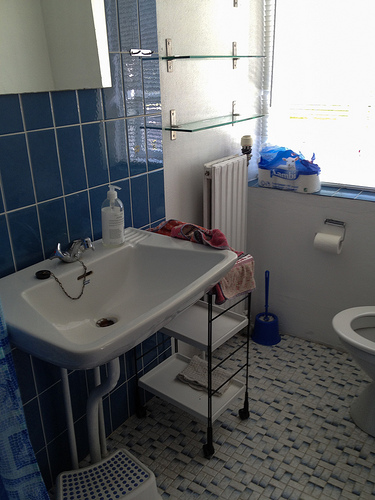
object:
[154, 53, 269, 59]
shelf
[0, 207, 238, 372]
sink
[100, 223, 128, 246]
soap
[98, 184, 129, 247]
bottle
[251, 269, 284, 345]
brush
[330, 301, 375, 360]
seat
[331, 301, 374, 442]
toilet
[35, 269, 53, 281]
stopper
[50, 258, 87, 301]
chain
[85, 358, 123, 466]
pipes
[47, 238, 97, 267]
faucet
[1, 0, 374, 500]
bathroom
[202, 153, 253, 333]
radiator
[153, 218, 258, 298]
towels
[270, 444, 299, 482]
tiles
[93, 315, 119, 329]
hole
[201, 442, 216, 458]
wheel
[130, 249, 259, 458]
holder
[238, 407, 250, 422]
wheel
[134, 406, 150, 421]
wheel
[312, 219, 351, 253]
holder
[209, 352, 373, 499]
floor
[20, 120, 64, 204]
tiles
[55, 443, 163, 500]
stool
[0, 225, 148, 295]
ledge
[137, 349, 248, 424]
tray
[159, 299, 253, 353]
tray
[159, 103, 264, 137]
racks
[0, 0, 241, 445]
wall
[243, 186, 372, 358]
wall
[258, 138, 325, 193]
paper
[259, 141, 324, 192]
packaging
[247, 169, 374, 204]
sill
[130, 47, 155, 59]
hook